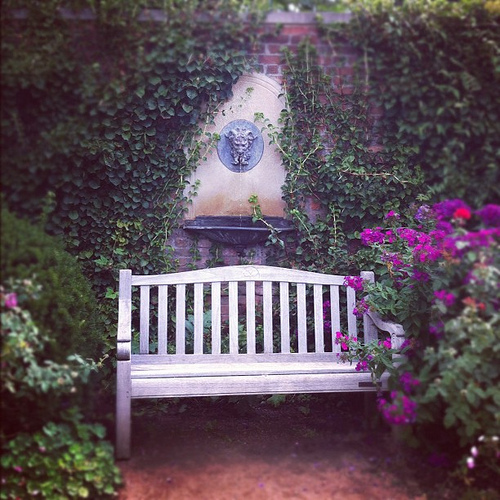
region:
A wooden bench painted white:
[107, 260, 412, 454]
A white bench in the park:
[112, 264, 437, 456]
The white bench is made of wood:
[110, 264, 425, 451]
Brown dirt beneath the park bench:
[151, 422, 392, 498]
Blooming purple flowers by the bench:
[342, 209, 495, 429]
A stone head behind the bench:
[213, 116, 277, 180]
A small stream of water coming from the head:
[232, 151, 253, 228]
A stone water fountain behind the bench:
[191, 115, 302, 247]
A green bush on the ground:
[10, 417, 109, 492]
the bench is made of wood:
[114, 268, 390, 457]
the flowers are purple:
[340, 195, 497, 430]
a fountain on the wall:
[221, 120, 260, 166]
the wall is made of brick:
[250, 14, 415, 168]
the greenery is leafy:
[2, 211, 497, 494]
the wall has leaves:
[4, 1, 496, 241]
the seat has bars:
[132, 286, 358, 354]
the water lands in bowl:
[188, 215, 288, 242]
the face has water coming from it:
[216, 117, 260, 167]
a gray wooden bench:
[115, 268, 414, 455]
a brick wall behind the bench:
[5, 10, 498, 325]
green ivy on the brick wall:
[7, 8, 498, 341]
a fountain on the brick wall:
[175, 76, 302, 243]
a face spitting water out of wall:
[227, 130, 256, 169]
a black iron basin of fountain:
[187, 215, 289, 248]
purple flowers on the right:
[338, 195, 495, 426]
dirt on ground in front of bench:
[124, 420, 410, 498]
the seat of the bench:
[132, 358, 389, 398]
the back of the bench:
[129, 270, 377, 355]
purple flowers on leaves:
[365, 228, 496, 269]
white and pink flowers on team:
[460, 441, 478, 465]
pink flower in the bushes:
[454, 208, 472, 222]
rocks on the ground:
[289, 438, 299, 460]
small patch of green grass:
[286, 416, 327, 432]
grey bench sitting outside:
[116, 270, 402, 458]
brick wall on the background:
[171, 239, 275, 261]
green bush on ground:
[1, 254, 87, 350]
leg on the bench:
[112, 358, 133, 463]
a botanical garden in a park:
[1, 2, 496, 496]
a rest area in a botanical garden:
[2, 1, 497, 498]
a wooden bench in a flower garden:
[114, 268, 404, 460]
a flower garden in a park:
[2, 1, 497, 498]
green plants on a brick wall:
[1, 0, 498, 198]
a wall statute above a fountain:
[213, 119, 265, 173]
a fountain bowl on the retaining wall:
[181, 213, 297, 248]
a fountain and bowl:
[181, 118, 297, 253]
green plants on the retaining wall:
[3, 2, 167, 209]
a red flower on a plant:
[452, 206, 473, 222]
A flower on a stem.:
[363, 230, 370, 238]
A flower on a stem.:
[437, 287, 446, 296]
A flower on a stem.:
[446, 293, 455, 302]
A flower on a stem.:
[404, 370, 409, 380]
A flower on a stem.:
[401, 383, 406, 388]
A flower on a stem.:
[408, 380, 415, 385]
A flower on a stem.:
[441, 202, 456, 209]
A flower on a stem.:
[410, 230, 421, 241]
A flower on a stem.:
[9, 292, 20, 305]